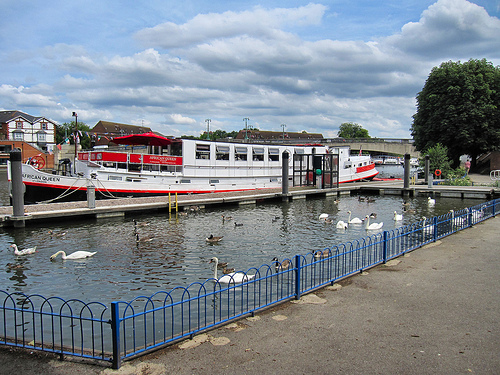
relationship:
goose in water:
[9, 242, 38, 255] [0, 192, 499, 352]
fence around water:
[1, 198, 499, 369] [0, 192, 499, 352]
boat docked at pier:
[7, 138, 380, 195] [0, 179, 500, 223]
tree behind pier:
[410, 57, 500, 173] [0, 179, 500, 223]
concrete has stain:
[0, 213, 499, 375] [272, 313, 288, 322]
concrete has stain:
[0, 213, 499, 375] [210, 336, 231, 346]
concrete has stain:
[0, 213, 499, 375] [383, 259, 402, 267]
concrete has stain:
[0, 213, 499, 375] [226, 323, 237, 329]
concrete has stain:
[0, 213, 499, 375] [179, 332, 209, 349]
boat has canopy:
[7, 138, 380, 195] [113, 131, 173, 147]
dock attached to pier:
[364, 184, 499, 199] [0, 179, 500, 223]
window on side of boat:
[195, 143, 211, 160] [7, 138, 380, 195]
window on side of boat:
[215, 144, 230, 161] [7, 138, 380, 195]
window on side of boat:
[235, 146, 249, 161] [7, 138, 380, 195]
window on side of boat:
[252, 148, 264, 162] [7, 138, 380, 195]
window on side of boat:
[268, 148, 280, 163] [7, 138, 380, 195]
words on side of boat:
[21, 172, 62, 183] [7, 138, 380, 195]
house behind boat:
[0, 110, 57, 154] [7, 138, 380, 195]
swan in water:
[50, 250, 98, 261] [0, 192, 499, 352]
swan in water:
[208, 257, 256, 284] [0, 192, 499, 352]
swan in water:
[347, 210, 365, 225] [0, 192, 499, 352]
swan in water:
[420, 216, 435, 234] [0, 192, 499, 352]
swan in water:
[448, 209, 464, 225] [0, 192, 499, 352]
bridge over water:
[215, 138, 422, 159] [1, 164, 423, 208]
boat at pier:
[7, 138, 380, 195] [0, 179, 500, 223]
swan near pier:
[208, 257, 256, 284] [0, 179, 500, 223]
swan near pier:
[420, 216, 435, 234] [0, 179, 500, 223]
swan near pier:
[448, 209, 464, 225] [0, 179, 500, 223]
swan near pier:
[347, 210, 365, 225] [0, 179, 500, 223]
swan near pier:
[50, 250, 98, 261] [0, 179, 500, 223]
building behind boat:
[89, 120, 154, 149] [7, 138, 380, 195]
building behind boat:
[234, 129, 325, 143] [7, 138, 380, 195]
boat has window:
[7, 138, 380, 195] [195, 143, 211, 160]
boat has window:
[7, 138, 380, 195] [215, 144, 230, 161]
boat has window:
[7, 138, 380, 195] [235, 146, 249, 161]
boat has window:
[7, 138, 380, 195] [252, 148, 264, 162]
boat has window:
[7, 138, 380, 195] [268, 148, 280, 163]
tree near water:
[410, 57, 500, 173] [0, 192, 499, 352]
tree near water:
[410, 57, 500, 173] [1, 164, 423, 208]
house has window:
[0, 110, 57, 154] [17, 122, 23, 129]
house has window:
[0, 110, 57, 154] [14, 132, 24, 139]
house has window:
[0, 110, 57, 154] [41, 123, 47, 129]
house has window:
[0, 110, 57, 154] [39, 134, 47, 141]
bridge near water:
[215, 138, 422, 159] [1, 164, 423, 208]